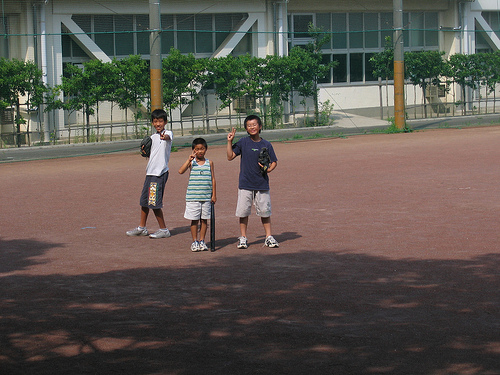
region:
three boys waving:
[130, 102, 290, 265]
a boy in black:
[227, 100, 287, 258]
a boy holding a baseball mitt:
[223, 108, 290, 170]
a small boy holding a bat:
[182, 130, 222, 260]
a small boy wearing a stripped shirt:
[183, 135, 215, 197]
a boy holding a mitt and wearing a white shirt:
[116, 97, 176, 252]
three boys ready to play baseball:
[107, 102, 418, 302]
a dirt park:
[0, 250, 372, 365]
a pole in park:
[383, 0, 421, 139]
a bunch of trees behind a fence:
[0, 69, 499, 121]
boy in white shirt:
[112, 93, 187, 176]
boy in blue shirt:
[229, 113, 300, 188]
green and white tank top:
[180, 153, 241, 215]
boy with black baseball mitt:
[124, 91, 195, 186]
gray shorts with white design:
[118, 155, 175, 215]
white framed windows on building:
[317, 20, 462, 100]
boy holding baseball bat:
[187, 133, 230, 253]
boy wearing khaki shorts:
[233, 121, 305, 269]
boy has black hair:
[139, 101, 179, 163]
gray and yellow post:
[375, 24, 422, 149]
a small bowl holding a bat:
[176, 134, 219, 260]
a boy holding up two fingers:
[220, 112, 300, 248]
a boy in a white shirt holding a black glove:
[122, 105, 180, 249]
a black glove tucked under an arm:
[254, 147, 280, 178]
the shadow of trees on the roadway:
[0, 241, 494, 367]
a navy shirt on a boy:
[229, 129, 278, 189]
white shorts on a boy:
[174, 198, 218, 224]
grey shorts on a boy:
[132, 168, 173, 212]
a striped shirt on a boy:
[180, 151, 221, 208]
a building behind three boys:
[9, 3, 492, 173]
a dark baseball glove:
[257, 148, 269, 170]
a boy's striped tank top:
[181, 157, 213, 198]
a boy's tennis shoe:
[260, 235, 280, 245]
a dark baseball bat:
[205, 195, 215, 250]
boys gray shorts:
[232, 190, 272, 216]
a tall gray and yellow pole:
[387, 2, 410, 124]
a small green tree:
[405, 50, 445, 117]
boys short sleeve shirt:
[143, 130, 172, 176]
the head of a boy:
[242, 114, 267, 137]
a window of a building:
[291, 14, 315, 39]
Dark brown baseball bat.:
[205, 203, 218, 249]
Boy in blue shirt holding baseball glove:
[256, 145, 266, 171]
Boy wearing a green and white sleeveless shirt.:
[186, 155, 211, 200]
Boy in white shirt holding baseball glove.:
[130, 125, 152, 160]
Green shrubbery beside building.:
[51, 44, 390, 120]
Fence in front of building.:
[21, 79, 353, 130]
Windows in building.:
[319, 15, 404, 89]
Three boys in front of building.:
[125, 104, 305, 254]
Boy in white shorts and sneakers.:
[186, 197, 216, 254]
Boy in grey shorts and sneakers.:
[231, 190, 285, 254]